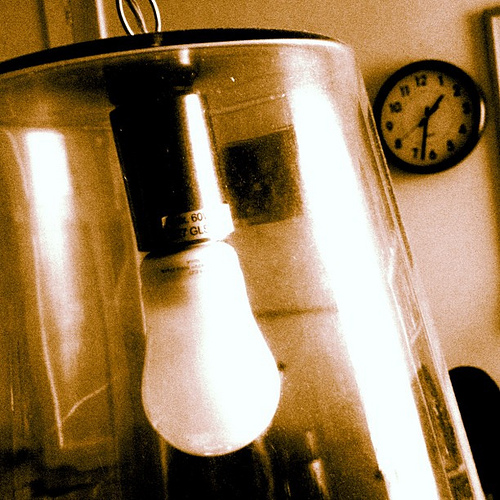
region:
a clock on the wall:
[373, 60, 484, 169]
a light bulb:
[148, 241, 263, 439]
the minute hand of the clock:
[416, 112, 426, 160]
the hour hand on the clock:
[430, 97, 444, 114]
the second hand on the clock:
[396, 123, 422, 147]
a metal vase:
[3, 48, 448, 482]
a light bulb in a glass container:
[4, 70, 456, 493]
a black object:
[443, 369, 497, 469]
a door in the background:
[30, 220, 135, 480]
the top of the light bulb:
[122, 103, 229, 200]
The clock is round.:
[364, 42, 494, 181]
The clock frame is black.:
[362, 55, 489, 180]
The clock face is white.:
[368, 47, 493, 185]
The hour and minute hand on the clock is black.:
[366, 42, 498, 179]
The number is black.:
[410, 68, 431, 91]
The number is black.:
[396, 80, 414, 101]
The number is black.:
[383, 93, 407, 115]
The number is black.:
[379, 114, 399, 137]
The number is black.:
[391, 130, 410, 152]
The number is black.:
[444, 79, 465, 106]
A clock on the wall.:
[372, 56, 488, 176]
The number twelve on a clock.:
[410, 67, 426, 88]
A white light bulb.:
[105, 82, 280, 458]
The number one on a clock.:
[432, 68, 443, 85]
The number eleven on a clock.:
[397, 80, 412, 99]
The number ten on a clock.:
[386, 97, 403, 114]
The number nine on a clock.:
[382, 116, 394, 133]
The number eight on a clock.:
[391, 133, 405, 150]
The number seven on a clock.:
[410, 142, 420, 161]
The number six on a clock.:
[428, 145, 439, 161]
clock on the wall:
[373, 64, 492, 178]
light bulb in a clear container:
[0, 43, 484, 498]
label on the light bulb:
[153, 251, 226, 284]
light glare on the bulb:
[176, 105, 231, 227]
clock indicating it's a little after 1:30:
[364, 50, 496, 188]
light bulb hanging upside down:
[107, 63, 304, 493]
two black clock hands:
[417, 83, 445, 160]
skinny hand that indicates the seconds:
[391, 123, 423, 149]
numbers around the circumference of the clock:
[381, 63, 479, 168]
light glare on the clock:
[475, 92, 490, 135]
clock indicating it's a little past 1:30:
[371, 57, 489, 188]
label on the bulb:
[147, 257, 207, 285]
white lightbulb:
[128, 244, 287, 459]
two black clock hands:
[389, 82, 462, 164]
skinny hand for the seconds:
[395, 125, 422, 147]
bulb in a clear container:
[1, 40, 471, 497]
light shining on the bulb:
[185, 104, 225, 216]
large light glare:
[286, 78, 474, 498]